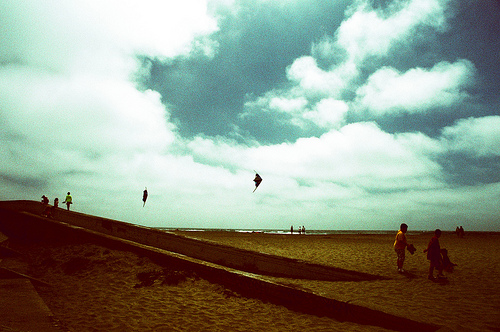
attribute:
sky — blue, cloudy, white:
[1, 0, 498, 229]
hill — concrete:
[1, 199, 451, 330]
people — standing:
[41, 190, 71, 216]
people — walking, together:
[289, 222, 463, 282]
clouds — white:
[0, 2, 499, 231]